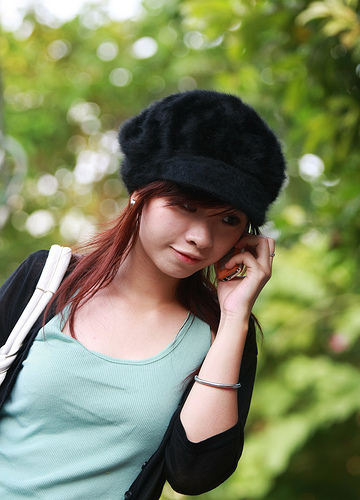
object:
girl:
[0, 88, 284, 496]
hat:
[118, 89, 285, 225]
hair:
[41, 182, 156, 334]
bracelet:
[193, 374, 242, 393]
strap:
[36, 244, 75, 381]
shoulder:
[0, 243, 90, 301]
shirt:
[0, 288, 210, 496]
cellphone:
[217, 230, 253, 283]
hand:
[216, 234, 275, 314]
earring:
[128, 189, 139, 209]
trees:
[15, 17, 344, 94]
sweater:
[0, 249, 257, 497]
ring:
[266, 251, 280, 261]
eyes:
[166, 193, 199, 213]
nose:
[184, 213, 213, 249]